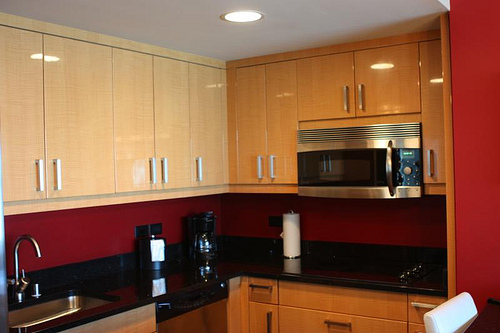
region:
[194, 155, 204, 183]
silver handle on the cabinet door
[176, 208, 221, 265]
black coffee maker on the counter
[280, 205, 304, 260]
white paper towels on the counter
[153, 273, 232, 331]
black and silver dishwasher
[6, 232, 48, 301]
silver faucet by the sink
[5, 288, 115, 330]
silver sink in the counter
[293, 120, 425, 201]
silver and black microwave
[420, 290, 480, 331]
white kitchen chair at the table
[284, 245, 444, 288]
black stove on the counter with knobs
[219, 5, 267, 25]
white light on the ceiling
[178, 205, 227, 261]
small black coffee maker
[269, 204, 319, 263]
silver paper towel holder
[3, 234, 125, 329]
stainless steel sink with tall faucet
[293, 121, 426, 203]
silver chrome microwave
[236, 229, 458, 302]
black poly counter tops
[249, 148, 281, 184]
two silver cabinet handles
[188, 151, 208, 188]
long rectangular cabinet handle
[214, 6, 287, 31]
over head recessed light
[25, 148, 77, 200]
pair of cabinet handles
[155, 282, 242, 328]
chrome and black dishwasher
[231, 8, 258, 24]
light on the ceiling.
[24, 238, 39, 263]
faucet on the sink.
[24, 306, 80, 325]
basin of the sink.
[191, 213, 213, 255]
coffee pot on counter.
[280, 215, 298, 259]
roll of paper towels.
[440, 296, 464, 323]
chair near the table.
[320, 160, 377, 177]
window on the microwave.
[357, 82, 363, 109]
handle on the cupboard.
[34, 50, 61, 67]
reflection on the cupboard.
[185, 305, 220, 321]
front of the dishwasher.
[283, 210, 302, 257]
a paper towel roll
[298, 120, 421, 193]
a silver microwave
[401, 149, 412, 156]
a digital display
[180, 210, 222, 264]
a black coffee maker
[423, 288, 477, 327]
a white chair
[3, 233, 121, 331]
a silver kitchen sink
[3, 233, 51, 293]
a silver kitchen faucet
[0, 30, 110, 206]
a wooden cabinet with metal handles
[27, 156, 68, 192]
metal handles to a wooden cabinet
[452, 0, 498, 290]
a dark red wall